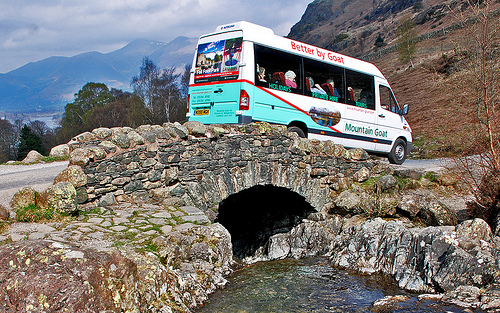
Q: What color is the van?
A: White and blue.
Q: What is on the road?
A: The van.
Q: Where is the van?
A: On the road.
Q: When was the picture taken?
A: Daytime.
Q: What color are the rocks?
A: Gray.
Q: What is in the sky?
A: Clouds.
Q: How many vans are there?
A: One.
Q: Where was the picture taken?
A: On a road.